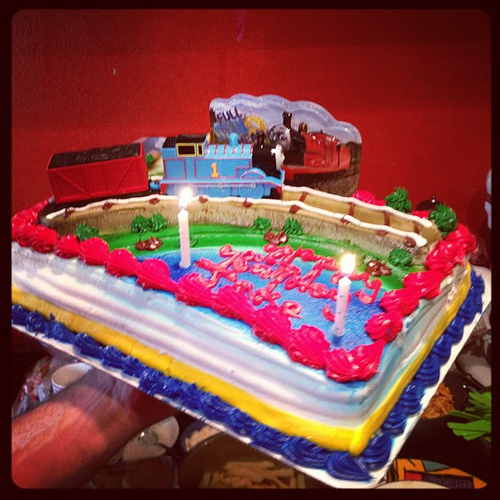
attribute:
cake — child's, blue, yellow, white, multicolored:
[8, 90, 494, 489]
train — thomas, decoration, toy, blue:
[157, 130, 294, 205]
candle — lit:
[174, 186, 199, 272]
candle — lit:
[327, 251, 360, 341]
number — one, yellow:
[206, 158, 224, 183]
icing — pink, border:
[12, 195, 480, 386]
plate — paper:
[368, 454, 495, 491]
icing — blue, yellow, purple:
[10, 264, 487, 483]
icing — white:
[10, 236, 474, 431]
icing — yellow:
[10, 259, 474, 459]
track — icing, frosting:
[41, 172, 442, 255]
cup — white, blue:
[47, 360, 99, 397]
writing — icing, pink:
[189, 241, 384, 324]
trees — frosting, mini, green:
[73, 182, 457, 272]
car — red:
[41, 134, 152, 210]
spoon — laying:
[136, 427, 187, 460]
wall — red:
[11, 8, 495, 353]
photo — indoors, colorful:
[1, 0, 500, 499]